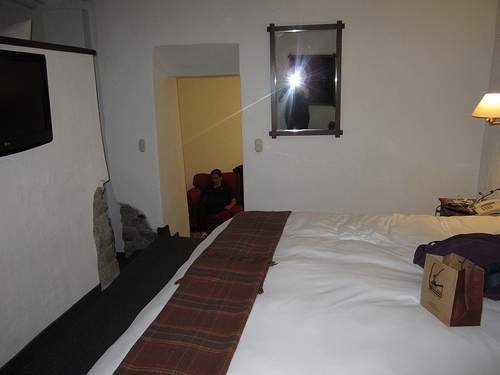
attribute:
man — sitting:
[194, 167, 239, 230]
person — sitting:
[187, 165, 233, 239]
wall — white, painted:
[100, 6, 497, 219]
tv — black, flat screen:
[2, 44, 64, 174]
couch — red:
[186, 167, 244, 232]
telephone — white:
[469, 189, 499, 217]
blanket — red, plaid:
[125, 182, 332, 354]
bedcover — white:
[304, 227, 393, 359]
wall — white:
[252, 18, 393, 153]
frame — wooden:
[259, 19, 349, 33]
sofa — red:
[187, 171, 242, 232]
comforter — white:
[207, 221, 429, 374]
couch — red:
[186, 172, 243, 230]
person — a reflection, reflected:
[281, 69, 313, 127]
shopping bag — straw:
[420, 251, 484, 327]